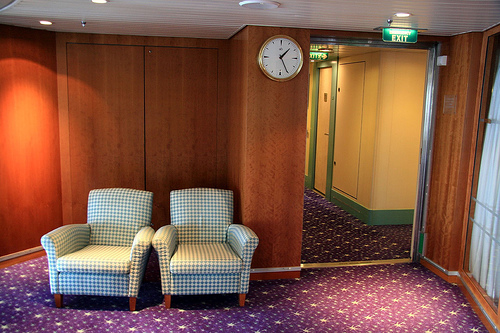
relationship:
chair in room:
[39, 189, 156, 311] [1, 1, 499, 332]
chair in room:
[151, 187, 260, 308] [1, 1, 499, 332]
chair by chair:
[39, 189, 156, 311] [151, 187, 260, 308]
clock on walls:
[257, 35, 305, 83] [0, 24, 482, 283]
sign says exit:
[381, 28, 417, 44] [392, 35, 408, 42]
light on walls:
[0, 57, 115, 271] [0, 24, 482, 283]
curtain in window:
[467, 63, 499, 300] [458, 25, 499, 332]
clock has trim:
[257, 35, 305, 83] [258, 34, 304, 82]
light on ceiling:
[39, 19, 52, 26] [1, 0, 498, 41]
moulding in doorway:
[312, 37, 439, 265] [302, 33, 429, 270]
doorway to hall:
[302, 33, 429, 270] [303, 42, 381, 263]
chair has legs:
[39, 189, 156, 311] [54, 292, 135, 310]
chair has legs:
[151, 187, 260, 308] [164, 294, 246, 308]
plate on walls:
[442, 95, 458, 112] [0, 24, 482, 283]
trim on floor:
[301, 258, 413, 269] [0, 186, 488, 332]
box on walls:
[436, 56, 448, 66] [0, 24, 482, 283]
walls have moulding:
[0, 24, 482, 283] [312, 37, 439, 265]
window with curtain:
[458, 25, 499, 332] [467, 63, 499, 300]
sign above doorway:
[381, 28, 417, 44] [302, 33, 429, 270]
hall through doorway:
[303, 42, 381, 263] [302, 33, 429, 270]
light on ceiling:
[93, 1, 108, 5] [1, 0, 498, 41]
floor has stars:
[0, 186, 488, 332] [278, 281, 313, 333]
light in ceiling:
[39, 19, 52, 26] [1, 0, 498, 41]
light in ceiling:
[93, 1, 108, 5] [1, 0, 498, 41]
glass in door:
[467, 34, 498, 304] [455, 21, 498, 331]